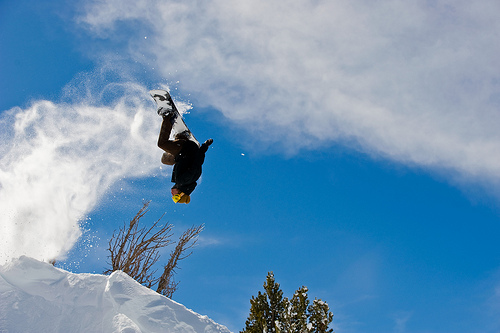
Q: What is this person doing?
A: A flip on a snowboard.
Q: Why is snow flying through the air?
A: The snow was agitated by the snowboarder.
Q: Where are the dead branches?
A: Behind the snowbank.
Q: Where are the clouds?
A: In the sky.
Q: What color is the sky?
A: Blue.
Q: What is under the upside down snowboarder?
A: A snowbank.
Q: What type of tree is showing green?
A: An evergreen.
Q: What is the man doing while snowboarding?
A: Tricks.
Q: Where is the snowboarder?
A: In the air.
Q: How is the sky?
A: Blue and cloudy.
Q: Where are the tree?
A: Behind the snow.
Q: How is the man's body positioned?
A: Upside down.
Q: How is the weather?
A: Sunny.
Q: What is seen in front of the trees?
A: A mound of snow.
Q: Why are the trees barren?
A: It's winter.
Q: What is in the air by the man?
A: Snow powder.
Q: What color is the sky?
A: Blue.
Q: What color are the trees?
A: Green.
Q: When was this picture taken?
A: Daytime.